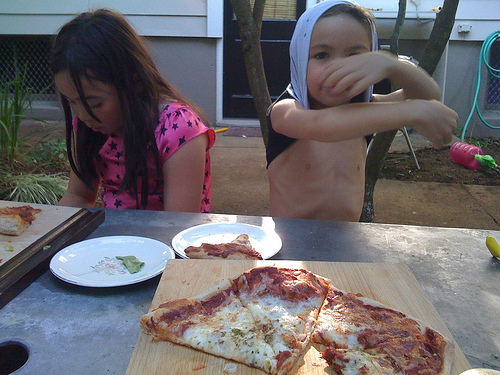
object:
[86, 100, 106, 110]
eyes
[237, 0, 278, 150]
tree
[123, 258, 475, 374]
board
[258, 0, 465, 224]
boy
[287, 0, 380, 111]
shirt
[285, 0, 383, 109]
head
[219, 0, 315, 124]
door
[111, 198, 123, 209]
star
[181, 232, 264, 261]
pizza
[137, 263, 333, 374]
pizza slice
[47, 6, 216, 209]
hair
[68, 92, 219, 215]
shirt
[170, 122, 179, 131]
star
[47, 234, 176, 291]
white plate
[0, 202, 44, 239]
pizza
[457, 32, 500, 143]
hose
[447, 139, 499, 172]
toy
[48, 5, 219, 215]
girl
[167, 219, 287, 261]
plate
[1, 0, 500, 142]
house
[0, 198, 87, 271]
block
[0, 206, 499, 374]
table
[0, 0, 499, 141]
side